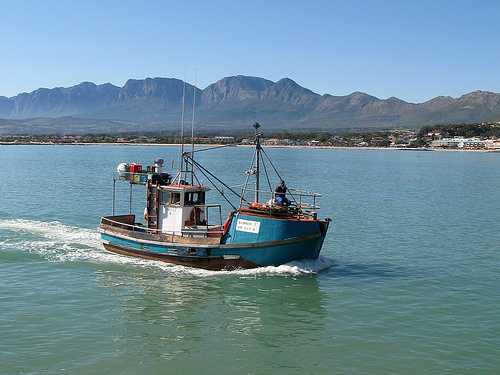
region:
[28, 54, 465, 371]
The photo was taken on the water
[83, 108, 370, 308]
There is one boat on the water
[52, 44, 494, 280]
There are mountains in the background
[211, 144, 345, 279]
There is one person visible on the boat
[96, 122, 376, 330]
The boat is blue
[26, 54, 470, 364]
The photo was taken in the daytime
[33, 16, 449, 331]
The photo was taken on a sunny day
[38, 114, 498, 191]
There are houses in the background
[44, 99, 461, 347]
There are no other boats on the water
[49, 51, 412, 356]
Waves form behind the boat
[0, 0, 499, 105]
a blue sky over the mountains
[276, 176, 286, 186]
the head of a man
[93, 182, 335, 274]
a blue boat on the water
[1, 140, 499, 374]
a blue body of water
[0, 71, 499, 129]
a row of mountains in the distance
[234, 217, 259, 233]
a white sign on the boat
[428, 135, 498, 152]
a building on the beach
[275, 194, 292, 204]
a pair of blue shorts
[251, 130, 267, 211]
a gray mast pole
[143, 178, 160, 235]
a small red ladder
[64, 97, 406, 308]
small boat on calm water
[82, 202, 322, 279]
small boat is turquoise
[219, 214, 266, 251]
small white sign on boat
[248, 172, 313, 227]
person sitting near front of boat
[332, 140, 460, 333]
calm blue water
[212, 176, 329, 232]
railing on front top of boat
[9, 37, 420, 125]
mountains are in the distant background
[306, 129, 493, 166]
buildings along the coastline in the distance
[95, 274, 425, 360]
boat's reflection in the water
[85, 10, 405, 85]
blue sky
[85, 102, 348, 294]
Boat is travel in the sea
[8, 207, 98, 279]
Choppy water formed with the passage of boat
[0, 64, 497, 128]
Mountain on the background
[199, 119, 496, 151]
City on the shore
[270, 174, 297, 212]
Person sit in front of boat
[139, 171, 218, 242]
Cabin of boat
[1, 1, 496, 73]
Sky is blue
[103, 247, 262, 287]
Base of boat is black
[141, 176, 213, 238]
Cabin is white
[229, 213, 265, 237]
White board on boat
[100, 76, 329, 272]
a boat on the water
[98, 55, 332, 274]
an old boat on the water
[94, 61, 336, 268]
a blue boat on the water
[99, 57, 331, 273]
a small boat on the water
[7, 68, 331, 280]
a boat moving through the water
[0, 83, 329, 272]
a small boat moving through the water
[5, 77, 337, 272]
a blue boat moving through the water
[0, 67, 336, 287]
an old boat moving through the water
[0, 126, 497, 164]
the distant shore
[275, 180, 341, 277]
the bow of the boat